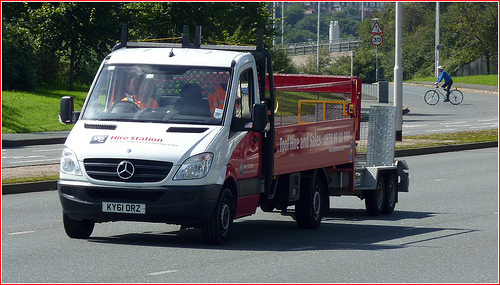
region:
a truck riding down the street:
[55, 23, 404, 233]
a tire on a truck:
[204, 185, 240, 244]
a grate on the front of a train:
[81, 158, 171, 180]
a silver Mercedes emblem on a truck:
[114, 159, 134, 180]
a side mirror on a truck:
[57, 93, 79, 127]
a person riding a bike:
[421, 63, 465, 104]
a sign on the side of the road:
[369, 15, 386, 88]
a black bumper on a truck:
[57, 182, 222, 217]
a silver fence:
[275, 38, 365, 55]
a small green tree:
[34, 1, 109, 92]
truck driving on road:
[76, 33, 411, 240]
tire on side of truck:
[202, 187, 237, 244]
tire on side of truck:
[298, 175, 330, 230]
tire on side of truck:
[368, 182, 400, 215]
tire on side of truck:
[386, 186, 398, 218]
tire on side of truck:
[67, 228, 92, 240]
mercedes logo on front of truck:
[113, 159, 140, 184]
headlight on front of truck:
[176, 153, 207, 187]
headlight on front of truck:
[64, 156, 83, 182]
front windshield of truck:
[113, 69, 218, 119]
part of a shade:
[301, 226, 354, 274]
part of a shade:
[365, 197, 429, 247]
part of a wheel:
[218, 216, 243, 246]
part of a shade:
[358, 211, 388, 234]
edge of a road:
[19, 171, 57, 198]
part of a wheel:
[204, 192, 241, 247]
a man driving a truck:
[93, 66, 157, 158]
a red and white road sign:
[364, 14, 387, 62]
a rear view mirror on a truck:
[43, 82, 78, 143]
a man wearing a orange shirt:
[93, 73, 158, 136]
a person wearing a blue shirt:
[427, 64, 457, 94]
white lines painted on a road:
[128, 221, 450, 284]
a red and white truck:
[83, 56, 373, 216]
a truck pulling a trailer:
[78, 54, 428, 219]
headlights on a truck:
[47, 147, 217, 187]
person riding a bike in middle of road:
[427, 64, 475, 114]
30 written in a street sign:
[369, 32, 386, 47]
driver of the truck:
[121, 69, 174, 116]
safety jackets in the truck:
[205, 85, 241, 118]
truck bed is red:
[269, 81, 379, 182]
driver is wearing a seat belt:
[120, 85, 143, 107]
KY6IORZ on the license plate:
[97, 199, 148, 216]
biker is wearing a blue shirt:
[438, 67, 456, 88]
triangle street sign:
[369, 18, 386, 38]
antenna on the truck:
[167, 36, 191, 59]